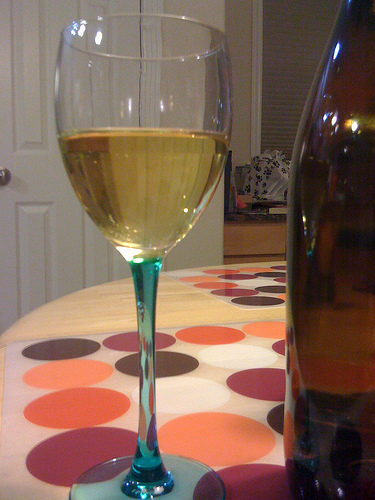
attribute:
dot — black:
[20, 336, 101, 361]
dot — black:
[116, 351, 199, 378]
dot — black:
[233, 294, 285, 308]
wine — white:
[54, 124, 230, 265]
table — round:
[2, 256, 374, 497]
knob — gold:
[0, 165, 14, 186]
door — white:
[2, 0, 138, 337]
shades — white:
[261, 1, 352, 155]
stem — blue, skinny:
[123, 262, 178, 493]